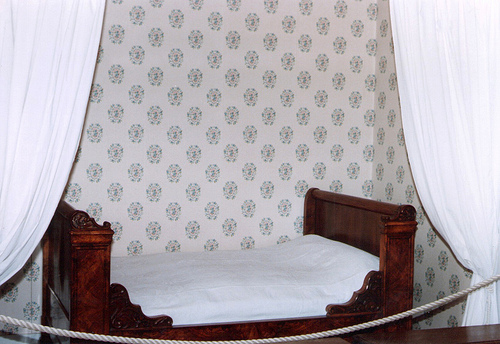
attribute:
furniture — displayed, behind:
[42, 203, 492, 288]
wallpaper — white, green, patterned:
[5, 9, 493, 339]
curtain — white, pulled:
[383, 3, 498, 324]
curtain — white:
[0, 5, 108, 285]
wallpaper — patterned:
[121, 15, 401, 237]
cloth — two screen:
[1, 36, 494, 227]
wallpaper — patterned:
[119, 8, 381, 178]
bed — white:
[32, 144, 434, 340]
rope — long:
[237, 316, 294, 339]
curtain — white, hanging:
[361, 13, 498, 303]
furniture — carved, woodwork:
[38, 183, 421, 340]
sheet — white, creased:
[110, 231, 379, 326]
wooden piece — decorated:
[326, 267, 380, 314]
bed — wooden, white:
[42, 157, 425, 342]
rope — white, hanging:
[1, 272, 499, 340]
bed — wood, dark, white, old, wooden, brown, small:
[41, 188, 416, 340]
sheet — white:
[108, 260, 340, 309]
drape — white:
[392, 4, 484, 319]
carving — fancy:
[337, 284, 387, 314]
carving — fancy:
[109, 289, 152, 331]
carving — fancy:
[67, 206, 99, 235]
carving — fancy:
[389, 201, 423, 222]